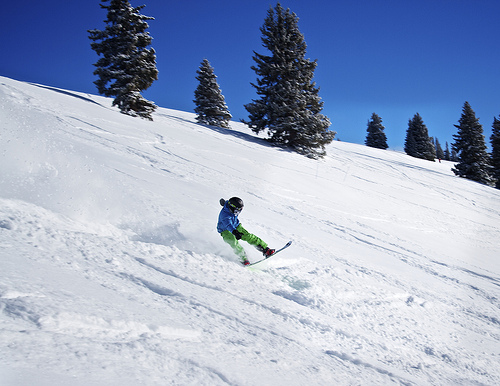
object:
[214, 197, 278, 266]
person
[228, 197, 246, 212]
helmet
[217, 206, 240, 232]
jacket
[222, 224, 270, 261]
pants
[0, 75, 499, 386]
snow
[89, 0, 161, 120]
trees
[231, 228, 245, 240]
gloves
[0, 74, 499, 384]
ground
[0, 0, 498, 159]
sky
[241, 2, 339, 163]
tree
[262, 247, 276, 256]
boots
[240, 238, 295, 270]
snowboard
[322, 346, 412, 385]
line